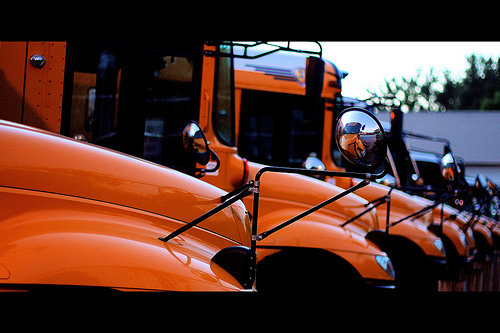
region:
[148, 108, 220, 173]
mirror on school bus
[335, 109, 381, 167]
mirror on school bus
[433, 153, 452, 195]
mirror on school bus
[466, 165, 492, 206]
mirror on school bus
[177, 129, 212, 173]
side mirror on bus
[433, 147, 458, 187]
side mirror on bus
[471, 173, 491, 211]
side mirror on bus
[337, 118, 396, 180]
side mirror on bus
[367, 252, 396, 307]
front light on bus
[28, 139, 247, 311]
the bus is orange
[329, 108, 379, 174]
reflection is on the mirror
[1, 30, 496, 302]
the buses are school buses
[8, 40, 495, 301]
the scene was taken outdoors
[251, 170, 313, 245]
the frame is mettallic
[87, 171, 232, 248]
there is reflection on the bus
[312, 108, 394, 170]
the mirror is concave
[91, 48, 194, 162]
no one is in the bus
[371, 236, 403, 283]
the lights rae curved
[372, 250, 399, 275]
the light is off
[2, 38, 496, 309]
many buses parked in a row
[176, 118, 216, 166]
mirror on side of bus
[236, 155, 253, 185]
turn signal on bus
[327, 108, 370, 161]
reflection of bus in mirror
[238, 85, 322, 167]
closed door on bus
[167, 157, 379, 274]
bracket holding mirror on vehicle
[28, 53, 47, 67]
silver bolt on side of bus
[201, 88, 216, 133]
handle on side of bus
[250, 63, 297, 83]
reflectors on top of bus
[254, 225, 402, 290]
fender well of bus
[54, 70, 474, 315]
Group of buses parked in a line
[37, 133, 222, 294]
The bus is yellow in color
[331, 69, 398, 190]
Reflection in the mirror on bus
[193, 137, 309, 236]
Black pole holding up a mirror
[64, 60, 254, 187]
Large door on side of bus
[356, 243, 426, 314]
Front headlight on the bus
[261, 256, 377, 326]
The wheel is black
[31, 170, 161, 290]
The bus is clean no dirt on it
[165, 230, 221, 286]
Light reflecting on the bus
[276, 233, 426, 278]
Shadow on the bus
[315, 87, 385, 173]
mirror on school bus is shiny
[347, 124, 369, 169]
reflection of school bus in back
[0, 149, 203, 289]
bus is orange in color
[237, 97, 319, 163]
window on bus is dark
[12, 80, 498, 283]
busses are lined up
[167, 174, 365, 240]
rods that hold the mirror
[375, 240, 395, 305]
light for the bus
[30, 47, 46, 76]
metal knob on the bus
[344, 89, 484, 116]
trees are blurred in photo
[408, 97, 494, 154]
white building in background